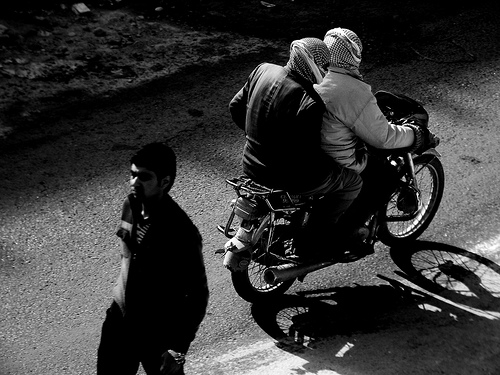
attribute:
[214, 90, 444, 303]
motorcycle — metallic, driving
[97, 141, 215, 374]
man — walking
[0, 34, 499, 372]
road — tarmacked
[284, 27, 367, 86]
headcovering — checkered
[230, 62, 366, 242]
clothes — dark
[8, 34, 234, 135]
area — shaded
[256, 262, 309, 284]
pipe — metal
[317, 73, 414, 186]
jacket — white, black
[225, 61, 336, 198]
jacket — black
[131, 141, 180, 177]
hair — black, dark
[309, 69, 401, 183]
jacket — light colored